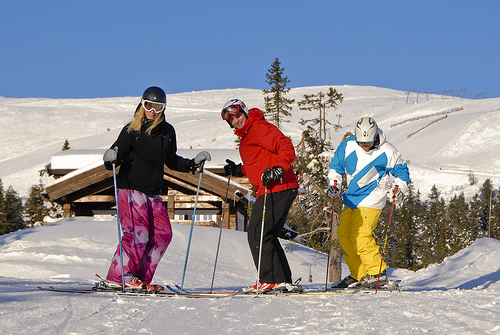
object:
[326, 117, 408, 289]
skier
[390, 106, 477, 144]
slopes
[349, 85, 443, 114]
slopes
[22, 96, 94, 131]
slopes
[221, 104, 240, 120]
goggles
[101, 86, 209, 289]
people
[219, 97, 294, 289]
people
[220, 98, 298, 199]
red jacket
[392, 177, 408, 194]
hand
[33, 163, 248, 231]
house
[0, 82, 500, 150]
hill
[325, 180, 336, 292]
ski poles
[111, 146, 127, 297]
ski poles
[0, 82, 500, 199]
mountain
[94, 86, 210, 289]
skiers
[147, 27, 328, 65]
clouds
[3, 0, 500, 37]
sky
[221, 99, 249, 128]
helmet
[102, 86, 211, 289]
woman skier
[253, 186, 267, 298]
poles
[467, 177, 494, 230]
trees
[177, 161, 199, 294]
ski poles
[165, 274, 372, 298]
skis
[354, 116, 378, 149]
head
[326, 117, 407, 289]
person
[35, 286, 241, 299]
skis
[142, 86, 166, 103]
helmet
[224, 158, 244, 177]
hand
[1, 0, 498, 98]
blue sky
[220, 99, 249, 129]
head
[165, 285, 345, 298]
ski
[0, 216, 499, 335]
hill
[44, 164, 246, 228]
resort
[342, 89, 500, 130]
ski lift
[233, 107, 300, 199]
jacket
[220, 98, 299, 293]
skier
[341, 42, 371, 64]
clouds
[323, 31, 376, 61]
clouds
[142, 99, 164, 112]
goggles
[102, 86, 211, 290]
woman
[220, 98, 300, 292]
woman